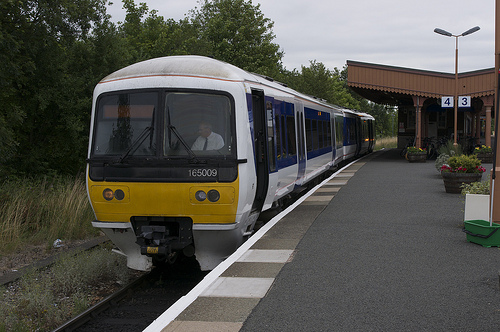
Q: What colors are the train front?
A: White and yellow.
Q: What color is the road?
A: Black.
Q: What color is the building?
A: Red.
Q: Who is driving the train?
A: A white man.